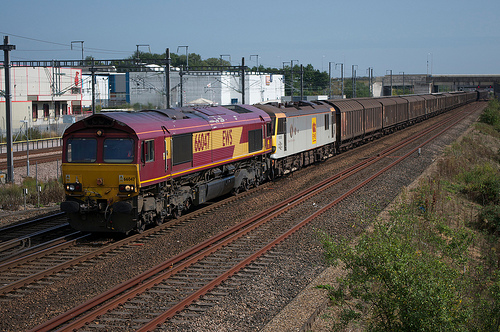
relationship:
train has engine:
[54, 84, 495, 235] [59, 105, 276, 233]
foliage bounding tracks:
[324, 97, 499, 330] [38, 100, 482, 330]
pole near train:
[4, 37, 19, 185] [54, 84, 495, 235]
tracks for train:
[38, 100, 482, 330] [54, 84, 495, 235]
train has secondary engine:
[54, 84, 495, 235] [263, 101, 342, 173]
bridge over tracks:
[433, 75, 498, 87] [38, 100, 482, 330]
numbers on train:
[192, 130, 211, 154] [54, 84, 495, 235]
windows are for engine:
[64, 136, 130, 167] [59, 105, 276, 233]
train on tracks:
[54, 84, 495, 235] [38, 100, 482, 330]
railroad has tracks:
[12, 82, 488, 329] [38, 100, 482, 330]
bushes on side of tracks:
[3, 178, 65, 207] [38, 100, 482, 330]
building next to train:
[1, 67, 289, 148] [54, 84, 495, 235]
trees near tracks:
[285, 62, 327, 94] [38, 100, 482, 330]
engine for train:
[59, 105, 276, 233] [54, 84, 495, 235]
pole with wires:
[4, 37, 19, 185] [7, 37, 422, 81]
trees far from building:
[285, 62, 327, 94] [1, 67, 289, 148]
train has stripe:
[54, 84, 495, 235] [140, 115, 276, 136]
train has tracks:
[54, 84, 495, 235] [38, 100, 482, 330]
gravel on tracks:
[15, 103, 483, 331] [38, 100, 482, 330]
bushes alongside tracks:
[3, 178, 65, 207] [38, 100, 482, 330]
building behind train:
[1, 67, 289, 148] [54, 84, 495, 235]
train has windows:
[54, 84, 495, 235] [64, 136, 130, 167]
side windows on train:
[140, 116, 336, 169] [54, 84, 495, 235]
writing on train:
[192, 131, 237, 149] [54, 84, 495, 235]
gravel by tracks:
[15, 103, 483, 331] [38, 100, 482, 330]